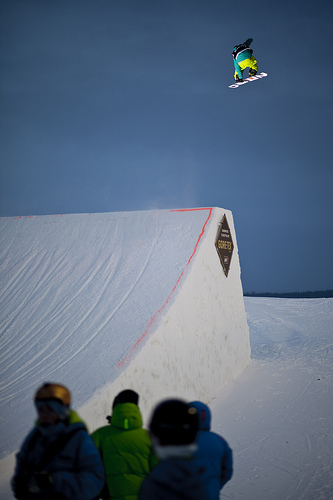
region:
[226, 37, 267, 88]
snowboarder in mid air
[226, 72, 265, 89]
snowboard with a mostly white bottom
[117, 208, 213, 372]
bright orange painting marking the edge and top of the ramp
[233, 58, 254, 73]
bright green pants on the snowboarder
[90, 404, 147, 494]
green jacket with a hood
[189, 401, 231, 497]
blue jacket with a hood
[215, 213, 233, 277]
sign on side of the ramp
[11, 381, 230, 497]
group of people watching below the ramp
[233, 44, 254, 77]
teal jacket on snowboarder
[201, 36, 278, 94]
man doing trick on snow board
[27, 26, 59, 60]
white clouds in blue sky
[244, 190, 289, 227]
white clouds in blue sky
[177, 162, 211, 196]
white clouds in blue sky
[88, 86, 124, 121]
white clouds in blue sky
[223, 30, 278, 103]
man doing trick off ramp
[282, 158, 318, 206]
white clouds in blue sky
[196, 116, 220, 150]
white clouds in blue sky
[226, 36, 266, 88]
The snowboarder is airborne.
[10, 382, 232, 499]
Spectators watch the snowboarder.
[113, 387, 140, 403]
The cap is black.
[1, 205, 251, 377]
A jump is in front of the spectators.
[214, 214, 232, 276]
A sign is on the jump.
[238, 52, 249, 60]
The jacket is green.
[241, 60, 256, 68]
The jacket is yellow.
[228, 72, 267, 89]
The snowboard has a graphic pattern on it.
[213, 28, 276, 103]
a skier in the air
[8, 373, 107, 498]
person wearing blue coat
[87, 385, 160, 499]
person wearing green coat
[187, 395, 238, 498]
person wearing blue coat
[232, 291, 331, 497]
field covered with snow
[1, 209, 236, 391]
a ramp covered with snow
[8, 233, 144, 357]
marks of skis on ramp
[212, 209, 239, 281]
a rhombus sign on ramp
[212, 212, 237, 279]
sign is color black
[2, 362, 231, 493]
a group of people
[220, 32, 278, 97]
person on a snowboard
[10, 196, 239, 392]
a snow half pike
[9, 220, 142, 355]
tracks on the pike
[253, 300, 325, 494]
snow on the ground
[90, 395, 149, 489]
person wearing a green jacket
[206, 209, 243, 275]
sign on the snow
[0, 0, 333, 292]
A clear blue sky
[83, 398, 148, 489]
A lime green coat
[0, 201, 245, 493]
A tall snow ramp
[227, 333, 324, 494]
tracks in the snow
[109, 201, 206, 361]
pink marking on ramp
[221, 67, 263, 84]
A colorful snow board